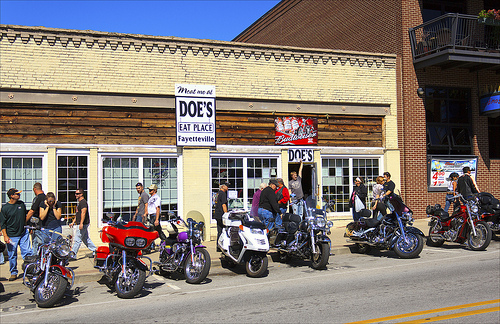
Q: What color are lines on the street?
A: Yellow.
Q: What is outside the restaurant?
A: Bikes.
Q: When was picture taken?
A: Daytime.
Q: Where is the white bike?
A: Middle.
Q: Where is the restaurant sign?
A: On the building.